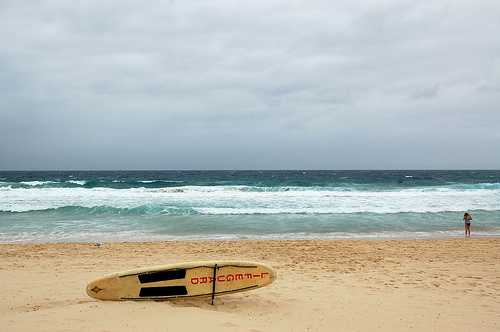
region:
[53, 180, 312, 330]
surfboard on the beach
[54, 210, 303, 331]
surfboard on the sand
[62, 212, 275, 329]
yellow surfboard on beach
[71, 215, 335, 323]
yellow surfboard on sand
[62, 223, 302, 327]
a lifeguard surfboard on beach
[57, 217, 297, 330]
a lifeguard surfboard on sand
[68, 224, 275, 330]
a yellow lifeguard surfboard on beach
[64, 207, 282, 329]
a yellow lifeguard surfboard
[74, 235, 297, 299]
a yellow lifeguard surfboard on sand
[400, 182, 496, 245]
someone standing on beach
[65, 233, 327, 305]
yellow flotation device on sand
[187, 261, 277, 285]
red letters on device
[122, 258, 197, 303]
black handles on device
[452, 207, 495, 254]
person out near water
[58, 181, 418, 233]
surf is rough and wavy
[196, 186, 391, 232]
waves are white and heavy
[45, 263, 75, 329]
sand is light brown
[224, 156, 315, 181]
water in distance is dark blue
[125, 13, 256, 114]
sky is grey and cloudy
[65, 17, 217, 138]
thick clouds over water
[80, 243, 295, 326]
a lifeguard surfboard in the sand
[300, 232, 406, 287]
tracks in the sand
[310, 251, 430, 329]
brown sand on the shore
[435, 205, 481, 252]
woman standing on the shore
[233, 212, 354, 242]
water crashing on the shore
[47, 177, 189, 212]
white foamy water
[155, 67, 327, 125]
gray clouds in the sky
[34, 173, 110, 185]
white wave caps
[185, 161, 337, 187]
dark blue ocean water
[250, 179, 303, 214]
person in the ocean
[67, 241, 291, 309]
wood colored surfboard stuck in the sand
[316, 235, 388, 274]
tracks in the brown sand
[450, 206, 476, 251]
girl standing on the shore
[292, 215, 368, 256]
water crashing onto the shore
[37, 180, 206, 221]
white waves in the ocean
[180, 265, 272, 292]
red writing on the surfboard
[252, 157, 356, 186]
deep dark blue ocean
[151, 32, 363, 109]
clouds in the sky above the ocean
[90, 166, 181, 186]
white capped waves in the ocean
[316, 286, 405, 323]
clean brown sand on the beach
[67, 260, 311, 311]
Tan, black and red surfboard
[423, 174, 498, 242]
girl near beach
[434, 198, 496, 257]
girl on the sand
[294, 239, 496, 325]
brown sand with footprints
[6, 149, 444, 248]
blue and white ocean waves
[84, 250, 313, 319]
surfboard on the sand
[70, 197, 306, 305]
surfboard near beach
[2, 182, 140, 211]
white waves in ocean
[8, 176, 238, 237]
small waves in ocean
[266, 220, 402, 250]
water and sand mixed